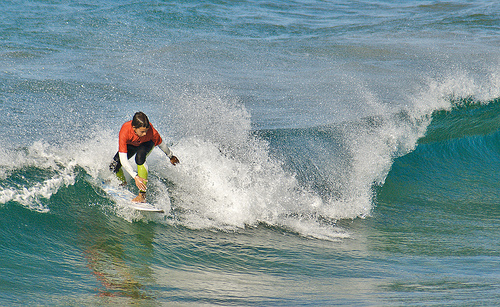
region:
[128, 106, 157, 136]
head of a person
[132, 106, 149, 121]
hair of a person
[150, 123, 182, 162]
arm of a person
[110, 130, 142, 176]
arm of a person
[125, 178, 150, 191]
hand of a person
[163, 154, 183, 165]
hand of a person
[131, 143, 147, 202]
leg of a person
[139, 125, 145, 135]
eye of a person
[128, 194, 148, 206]
leg of a person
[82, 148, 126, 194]
leg of a person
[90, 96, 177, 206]
A person surfing in the water.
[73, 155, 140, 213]
A person on a surfboard.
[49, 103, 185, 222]
The person is riding the wave.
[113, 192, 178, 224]
The surfboard is in the water.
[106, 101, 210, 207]
The person is wet.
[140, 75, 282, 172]
Water splashing in the ocean.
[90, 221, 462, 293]
The water is green.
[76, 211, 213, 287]
Reflection in the water of the surfer.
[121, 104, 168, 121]
The person hair is wet.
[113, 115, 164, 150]
person is wearing an orange shirt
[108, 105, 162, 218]
person is standing on a surfboad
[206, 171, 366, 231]
the wave is crashing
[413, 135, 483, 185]
ocean water is a clear blue green in color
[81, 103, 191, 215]
person is surfing in the ocean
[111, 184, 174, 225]
white surfboard in the water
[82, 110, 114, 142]
water spray from the surfboard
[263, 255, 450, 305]
water is smooth in front of the surfer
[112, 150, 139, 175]
surfer has white sleeves on their shirt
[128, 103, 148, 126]
person's hair is wet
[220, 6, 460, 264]
it is a big ocean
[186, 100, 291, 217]
it is a ocean waves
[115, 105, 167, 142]
boy wearing orange dress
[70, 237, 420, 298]
it is green ocean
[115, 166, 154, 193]
it is boy hand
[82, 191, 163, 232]
board color is white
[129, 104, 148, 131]
it is boy hear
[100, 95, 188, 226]
A person surfing a wave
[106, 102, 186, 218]
A person surfing a wave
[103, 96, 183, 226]
A person surfing a wave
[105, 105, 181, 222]
A person surfing a wave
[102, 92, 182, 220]
A person surfing a wave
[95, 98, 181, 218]
A person surfing a wave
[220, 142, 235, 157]
water droplet by the surfer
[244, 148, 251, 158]
water droplet by the surfer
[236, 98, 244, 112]
water droplet by the surfer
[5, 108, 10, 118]
water droplet by the surfer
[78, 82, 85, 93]
water droplet by the surfer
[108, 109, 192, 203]
The boy is surfing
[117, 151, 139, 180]
The white long sleeves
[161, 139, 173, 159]
The long white sleeve on the arm sticking out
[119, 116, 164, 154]
The red shirt on the surfer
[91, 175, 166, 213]
The white surfboard in the water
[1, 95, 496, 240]
The wave behind the surfer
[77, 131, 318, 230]
The water is splashing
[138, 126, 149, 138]
The face of the surfer